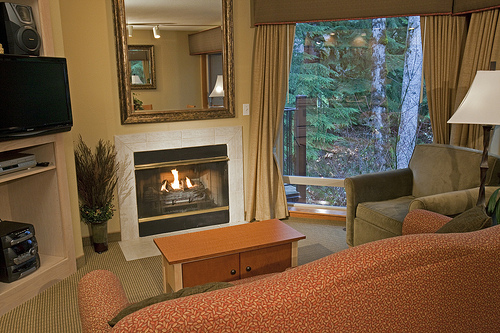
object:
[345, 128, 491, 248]
armchair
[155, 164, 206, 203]
fire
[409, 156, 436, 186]
couch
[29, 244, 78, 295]
shelf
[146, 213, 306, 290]
table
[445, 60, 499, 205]
lamp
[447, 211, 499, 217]
table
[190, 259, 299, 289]
cabinet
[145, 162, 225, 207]
logs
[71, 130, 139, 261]
plant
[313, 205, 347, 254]
floor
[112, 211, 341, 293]
coffee table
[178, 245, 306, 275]
cupboards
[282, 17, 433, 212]
window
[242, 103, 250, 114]
light switch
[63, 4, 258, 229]
wall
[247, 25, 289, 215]
tan curtain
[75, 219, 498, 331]
couch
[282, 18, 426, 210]
outdoor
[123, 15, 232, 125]
mirror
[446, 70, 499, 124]
lamp shade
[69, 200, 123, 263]
vase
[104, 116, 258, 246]
fireplace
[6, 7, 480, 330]
living room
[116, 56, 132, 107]
frame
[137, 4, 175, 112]
reflection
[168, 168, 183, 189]
flame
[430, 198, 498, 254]
pillow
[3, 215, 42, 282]
stereo